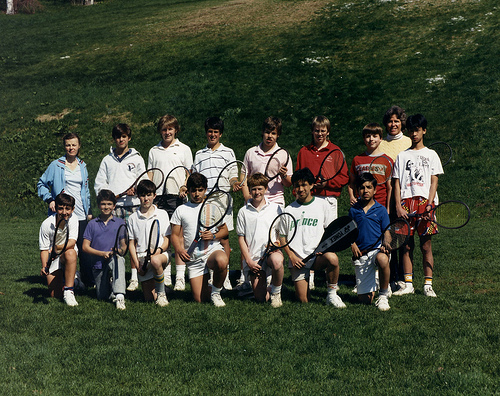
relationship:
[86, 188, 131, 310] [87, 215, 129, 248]
boy wearing shirt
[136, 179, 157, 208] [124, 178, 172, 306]
head of a boy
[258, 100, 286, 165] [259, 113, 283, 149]
boy has head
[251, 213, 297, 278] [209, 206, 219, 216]
racket with laces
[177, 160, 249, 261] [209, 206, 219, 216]
rackets with laces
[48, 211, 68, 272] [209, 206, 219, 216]
tennis racket with laces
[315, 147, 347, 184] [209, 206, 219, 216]
tennis racket with laces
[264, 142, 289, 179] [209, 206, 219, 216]
tennis racket with laces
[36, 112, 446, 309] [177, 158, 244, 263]
boys holding rackets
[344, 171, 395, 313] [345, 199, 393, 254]
boy has shirt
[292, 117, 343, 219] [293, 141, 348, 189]
boy has shirt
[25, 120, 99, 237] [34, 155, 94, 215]
coach has blue sweater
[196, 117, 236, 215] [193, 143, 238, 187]
boy in striped shirt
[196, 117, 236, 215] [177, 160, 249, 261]
boy with rackets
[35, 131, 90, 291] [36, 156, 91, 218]
person in jacket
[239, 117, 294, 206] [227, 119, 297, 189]
boy in pink shirt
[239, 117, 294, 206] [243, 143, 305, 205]
boy with tennis racket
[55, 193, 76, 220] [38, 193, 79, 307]
head of a boy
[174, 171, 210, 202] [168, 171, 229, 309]
head of boys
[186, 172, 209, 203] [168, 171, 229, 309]
head of boys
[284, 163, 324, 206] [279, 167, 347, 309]
head of boy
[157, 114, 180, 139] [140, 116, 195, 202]
head on boy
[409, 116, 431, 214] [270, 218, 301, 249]
boy holding racket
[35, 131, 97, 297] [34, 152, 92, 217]
woman wearing jacket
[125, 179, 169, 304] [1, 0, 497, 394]
boy kneeling on grass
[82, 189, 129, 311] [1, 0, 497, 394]
boy kneeling on grass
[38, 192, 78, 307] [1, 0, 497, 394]
boy kneeling on grass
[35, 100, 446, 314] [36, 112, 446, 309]
team of boys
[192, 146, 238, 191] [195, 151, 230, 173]
striped shirt has stripes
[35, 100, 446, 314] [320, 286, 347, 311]
team wearing shoes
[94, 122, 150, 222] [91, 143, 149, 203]
boy wearing hoodie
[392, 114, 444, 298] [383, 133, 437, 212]
boy wearing shirt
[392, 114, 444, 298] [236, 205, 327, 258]
boy holding racket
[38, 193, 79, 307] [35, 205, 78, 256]
boy wearing shirt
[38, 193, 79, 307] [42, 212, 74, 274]
boy holding tennis racket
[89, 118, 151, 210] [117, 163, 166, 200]
boy holding tennis racket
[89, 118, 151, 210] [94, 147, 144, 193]
boy wearing hoodie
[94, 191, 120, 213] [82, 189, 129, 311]
head of boy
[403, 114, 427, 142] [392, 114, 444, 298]
head of boy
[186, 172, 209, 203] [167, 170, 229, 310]
head of person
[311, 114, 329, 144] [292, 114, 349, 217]
head of boy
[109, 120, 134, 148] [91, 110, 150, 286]
head of boy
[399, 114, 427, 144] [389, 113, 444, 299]
head of boy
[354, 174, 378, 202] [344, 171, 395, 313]
head of boy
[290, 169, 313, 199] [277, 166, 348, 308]
head of boy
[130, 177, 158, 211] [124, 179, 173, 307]
head of boy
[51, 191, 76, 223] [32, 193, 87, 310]
head of boy